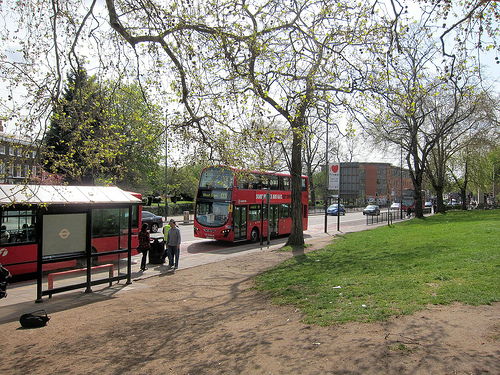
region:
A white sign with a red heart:
[325, 158, 341, 233]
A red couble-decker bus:
[190, 163, 312, 244]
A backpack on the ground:
[16, 304, 53, 331]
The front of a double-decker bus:
[190, 162, 231, 244]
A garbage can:
[143, 231, 168, 269]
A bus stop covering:
[1, 179, 141, 304]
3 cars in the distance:
[323, 197, 403, 222]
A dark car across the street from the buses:
[123, 209, 167, 236]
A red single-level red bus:
[0, 189, 147, 280]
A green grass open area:
[258, 207, 498, 321]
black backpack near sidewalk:
[18, 307, 53, 329]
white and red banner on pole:
[326, 159, 343, 193]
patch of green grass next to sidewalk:
[249, 202, 498, 333]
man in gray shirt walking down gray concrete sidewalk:
[163, 217, 183, 272]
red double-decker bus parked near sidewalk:
[190, 159, 312, 246]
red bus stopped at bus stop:
[0, 179, 146, 286]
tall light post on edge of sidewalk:
[318, 97, 333, 236]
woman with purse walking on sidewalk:
[135, 221, 153, 273]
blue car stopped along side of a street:
[324, 201, 347, 217]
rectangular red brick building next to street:
[313, 155, 438, 210]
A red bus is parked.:
[2, 181, 147, 275]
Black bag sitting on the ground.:
[14, 307, 54, 330]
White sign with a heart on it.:
[325, 160, 343, 235]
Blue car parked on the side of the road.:
[325, 202, 347, 217]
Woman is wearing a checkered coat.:
[134, 219, 154, 273]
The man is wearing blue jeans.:
[167, 219, 182, 271]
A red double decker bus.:
[193, 160, 317, 245]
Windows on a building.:
[337, 163, 359, 189]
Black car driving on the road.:
[360, 202, 379, 217]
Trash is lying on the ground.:
[285, 282, 375, 349]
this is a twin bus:
[194, 170, 289, 237]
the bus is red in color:
[198, 164, 285, 235]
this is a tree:
[285, 89, 314, 241]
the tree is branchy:
[213, 22, 349, 114]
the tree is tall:
[281, 125, 306, 241]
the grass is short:
[340, 235, 412, 311]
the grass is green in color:
[331, 230, 432, 308]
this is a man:
[167, 218, 180, 258]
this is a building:
[351, 160, 394, 191]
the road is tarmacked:
[193, 242, 205, 254]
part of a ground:
[212, 310, 252, 357]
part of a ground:
[358, 250, 410, 319]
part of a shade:
[188, 290, 238, 361]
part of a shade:
[198, 306, 228, 343]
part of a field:
[348, 238, 410, 322]